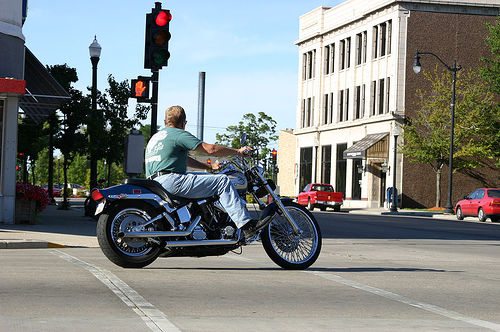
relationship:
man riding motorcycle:
[153, 95, 232, 196] [102, 175, 324, 260]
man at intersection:
[153, 95, 232, 196] [213, 266, 482, 331]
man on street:
[153, 95, 232, 196] [357, 219, 447, 277]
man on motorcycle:
[153, 95, 232, 196] [102, 175, 324, 260]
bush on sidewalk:
[30, 187, 43, 198] [53, 208, 83, 235]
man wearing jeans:
[153, 95, 232, 196] [176, 176, 253, 218]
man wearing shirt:
[153, 95, 232, 196] [150, 124, 193, 170]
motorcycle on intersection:
[102, 175, 324, 260] [213, 266, 482, 331]